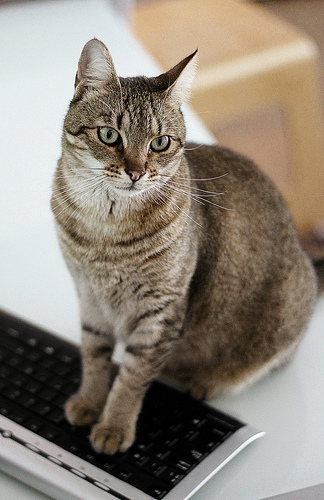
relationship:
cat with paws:
[45, 39, 311, 461] [59, 356, 137, 462]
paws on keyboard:
[59, 356, 137, 462] [3, 303, 266, 499]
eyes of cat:
[97, 124, 170, 155] [45, 39, 311, 461]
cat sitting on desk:
[45, 39, 311, 461] [3, 5, 312, 500]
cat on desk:
[45, 39, 311, 461] [3, 5, 312, 500]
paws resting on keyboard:
[59, 356, 137, 462] [3, 303, 266, 499]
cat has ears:
[45, 39, 311, 461] [83, 33, 195, 97]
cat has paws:
[45, 39, 311, 461] [59, 356, 137, 462]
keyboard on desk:
[3, 303, 266, 499] [3, 5, 312, 500]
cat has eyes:
[45, 39, 311, 461] [97, 124, 170, 155]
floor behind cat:
[137, 10, 323, 245] [45, 39, 311, 461]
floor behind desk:
[137, 10, 323, 245] [3, 5, 312, 500]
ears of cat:
[83, 33, 195, 97] [45, 39, 311, 461]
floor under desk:
[137, 10, 323, 245] [3, 5, 312, 500]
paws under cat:
[171, 364, 234, 400] [45, 39, 311, 461]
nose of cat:
[128, 168, 143, 182] [45, 39, 311, 461]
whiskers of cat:
[39, 158, 229, 227] [45, 39, 311, 461]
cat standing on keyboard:
[45, 39, 311, 461] [3, 303, 266, 499]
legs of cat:
[57, 256, 163, 454] [45, 39, 311, 461]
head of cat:
[58, 33, 204, 207] [45, 39, 311, 461]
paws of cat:
[59, 356, 137, 462] [45, 39, 311, 461]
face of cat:
[88, 113, 176, 190] [45, 39, 311, 461]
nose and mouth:
[128, 168, 143, 182] [120, 181, 141, 197]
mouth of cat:
[120, 181, 141, 197] [45, 39, 311, 461]